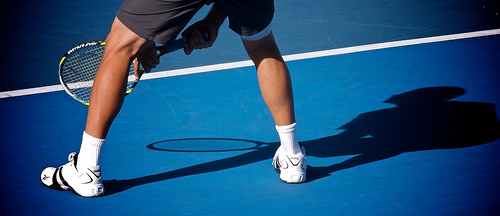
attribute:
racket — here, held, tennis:
[63, 32, 132, 106]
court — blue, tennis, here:
[297, 22, 449, 149]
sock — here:
[74, 137, 121, 169]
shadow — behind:
[338, 74, 451, 196]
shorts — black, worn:
[139, 3, 204, 43]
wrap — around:
[240, 19, 277, 51]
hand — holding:
[179, 22, 216, 53]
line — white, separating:
[313, 29, 393, 87]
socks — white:
[78, 132, 109, 156]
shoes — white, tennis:
[45, 151, 99, 197]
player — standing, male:
[104, 11, 280, 171]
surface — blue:
[149, 71, 213, 122]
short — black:
[135, 6, 181, 52]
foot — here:
[263, 137, 317, 173]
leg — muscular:
[107, 62, 134, 110]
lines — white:
[164, 54, 216, 76]